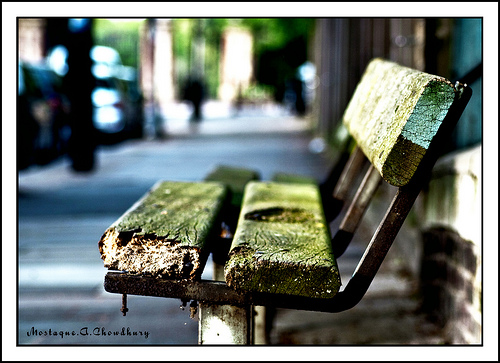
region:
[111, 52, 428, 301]
The bench is wood.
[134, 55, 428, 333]
The bench is empty.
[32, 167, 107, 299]
The street is empty.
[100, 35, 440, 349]
The sun is shining.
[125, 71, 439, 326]
The bench is old.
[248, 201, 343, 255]
A whole is in the seat.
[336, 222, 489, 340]
The bench is casting a shadow.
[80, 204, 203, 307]
The wood has a piece missing.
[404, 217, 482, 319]
The wall is brick.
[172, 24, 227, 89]
The trees are leafy.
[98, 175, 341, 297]
Two thick green wood slats on the seat part of the bench.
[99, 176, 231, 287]
Green wood slat of a bench that has been broken off on the end.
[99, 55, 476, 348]
A green wooden bench with metal frame.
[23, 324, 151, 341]
Black lettered name of the photographer.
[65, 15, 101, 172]
A tall black pole on the sidewalk.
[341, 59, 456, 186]
Worn back slat of a metal and wood bench.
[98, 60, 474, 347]
Green molding wood and metal bench.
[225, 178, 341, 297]
Moldy green slat on the bench beside a broken slat on the bottom.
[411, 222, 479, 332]
Black shadow on the bricks behind the bench.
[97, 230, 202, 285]
Brown broken piece of the wood on the bottom of the bench.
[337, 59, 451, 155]
back of wood bench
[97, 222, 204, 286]
broken edge of wood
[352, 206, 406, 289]
metal brace on bench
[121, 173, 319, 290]
two wood boards of bench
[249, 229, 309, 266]
worn surface of bench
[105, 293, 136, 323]
rusted metal bolt under bench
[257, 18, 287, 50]
blurred green tree leaves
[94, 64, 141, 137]
blurred car parked on street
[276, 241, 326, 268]
grain in wood board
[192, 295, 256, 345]
leg under metal brace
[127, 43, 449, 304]
old wooden bench along street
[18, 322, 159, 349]
photographers name in lower left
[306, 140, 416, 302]
rusty metal rails on bench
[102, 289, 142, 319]
bolt coming out of bench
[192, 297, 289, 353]
dirty white stand under bench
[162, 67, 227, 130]
outline of dark character on sidewalk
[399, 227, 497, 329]
red brick wall behind bench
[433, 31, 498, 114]
teal colored window panes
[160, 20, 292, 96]
blurry trees along sidewalk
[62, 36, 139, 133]
reflection off white colored vehicle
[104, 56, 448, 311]
bench on the ground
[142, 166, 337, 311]
sitting part of bench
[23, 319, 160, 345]
name in bottom left corner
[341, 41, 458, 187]
back part of bench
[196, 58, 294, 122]
blurry background of photo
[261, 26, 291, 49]
trees in the distance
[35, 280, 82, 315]
ground next to the bench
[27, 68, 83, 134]
car next to the curb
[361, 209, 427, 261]
pole on the bench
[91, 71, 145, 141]
car in the background